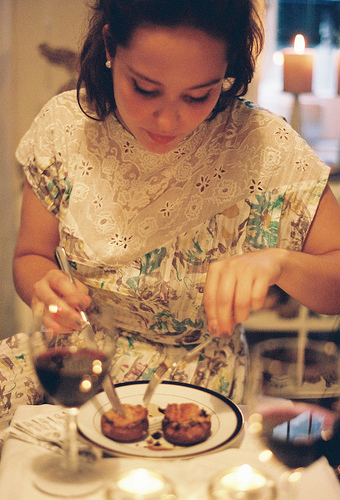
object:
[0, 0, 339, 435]
woman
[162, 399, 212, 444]
crab cake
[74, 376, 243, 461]
plate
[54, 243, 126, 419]
knife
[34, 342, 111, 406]
wine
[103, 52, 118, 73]
earring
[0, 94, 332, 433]
dress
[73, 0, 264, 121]
hair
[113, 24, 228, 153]
face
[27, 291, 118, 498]
glass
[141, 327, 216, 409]
fork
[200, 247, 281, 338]
hand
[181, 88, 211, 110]
eye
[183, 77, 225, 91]
eyebrow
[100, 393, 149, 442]
food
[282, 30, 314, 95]
candle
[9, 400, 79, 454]
napkin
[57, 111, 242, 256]
fabric